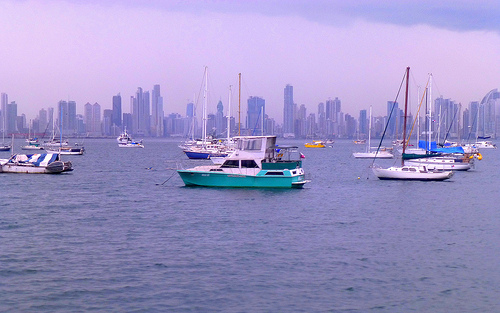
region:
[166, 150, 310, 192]
boat on the water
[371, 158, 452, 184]
boat on the water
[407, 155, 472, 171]
boat on the water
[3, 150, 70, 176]
boat on the water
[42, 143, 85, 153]
boat on the water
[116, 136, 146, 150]
boat on the water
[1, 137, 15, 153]
boat on the water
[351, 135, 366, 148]
boat on the water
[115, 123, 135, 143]
boat on the water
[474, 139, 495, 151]
boat on the water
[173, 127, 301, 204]
this is a ship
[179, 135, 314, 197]
the ship is on water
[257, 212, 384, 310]
this is the water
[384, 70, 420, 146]
this is the pole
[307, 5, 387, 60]
this is the sky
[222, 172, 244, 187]
the ship is blue in color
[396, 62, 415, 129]
the pole is red in color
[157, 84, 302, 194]
the ships are on the water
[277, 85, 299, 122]
this is a building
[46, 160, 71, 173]
this is the floater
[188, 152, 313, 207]
This is a boat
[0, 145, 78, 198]
This is a boat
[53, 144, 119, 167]
This is a boat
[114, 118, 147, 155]
This is a boat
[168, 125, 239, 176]
This is a boat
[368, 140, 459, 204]
This is a boat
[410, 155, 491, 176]
This is a boat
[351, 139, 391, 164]
This is a boat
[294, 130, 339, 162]
This is a boat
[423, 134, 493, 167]
This is a boat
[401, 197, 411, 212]
part of the sea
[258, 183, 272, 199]
part of a boat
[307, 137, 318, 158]
part of a building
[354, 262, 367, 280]
part of the sky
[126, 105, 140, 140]
part of a building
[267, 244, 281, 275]
edge of a sea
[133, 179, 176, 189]
part of a rope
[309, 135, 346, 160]
edge of a boat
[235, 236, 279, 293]
part of a water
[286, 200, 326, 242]
part of a watrer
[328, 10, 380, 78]
part of a xloud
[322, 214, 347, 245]
part of a water